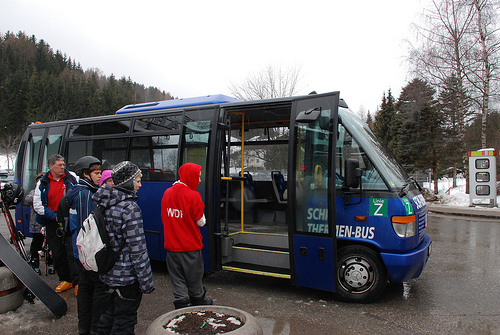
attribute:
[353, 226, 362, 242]
letter — White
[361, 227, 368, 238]
letter — White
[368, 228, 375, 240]
letter — White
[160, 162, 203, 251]
jacket — red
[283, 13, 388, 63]
clouds — white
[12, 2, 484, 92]
sky — blue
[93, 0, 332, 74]
sky — blue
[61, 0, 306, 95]
sky — blue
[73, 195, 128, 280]
backpack — White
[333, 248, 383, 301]
tire — front tire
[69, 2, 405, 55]
sky — blue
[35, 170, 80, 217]
shirt — red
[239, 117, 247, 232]
pole — yellow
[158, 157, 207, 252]
hoodie — red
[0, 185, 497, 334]
road — slick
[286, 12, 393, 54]
sky — blue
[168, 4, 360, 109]
clouds — white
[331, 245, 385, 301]
wheel — bus wheel, Black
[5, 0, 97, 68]
clouds — white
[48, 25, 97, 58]
clouds — white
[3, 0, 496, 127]
sky — blue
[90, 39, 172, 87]
cloud — white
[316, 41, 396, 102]
clouds — white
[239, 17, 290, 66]
clouds — white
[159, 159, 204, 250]
hoodie — reddish orange